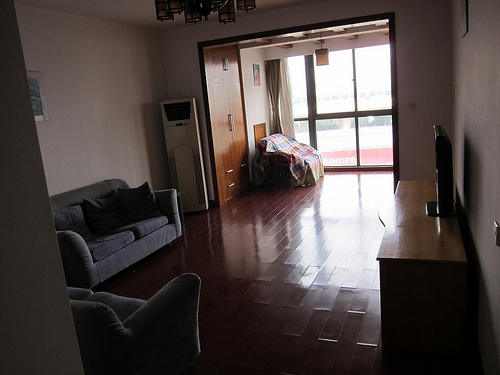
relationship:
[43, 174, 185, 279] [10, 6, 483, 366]
couch in living room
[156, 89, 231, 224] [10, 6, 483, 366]
heater in living room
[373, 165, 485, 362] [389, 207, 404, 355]
cabinet has drawers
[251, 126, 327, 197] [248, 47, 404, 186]
chair by window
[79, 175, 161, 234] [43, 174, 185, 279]
pillows on couch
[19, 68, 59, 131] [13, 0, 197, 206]
artwork on wall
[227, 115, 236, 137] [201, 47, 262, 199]
handles on closet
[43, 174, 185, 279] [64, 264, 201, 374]
sofa next to loveseat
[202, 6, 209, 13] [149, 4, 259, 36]
lamp shade on light fixture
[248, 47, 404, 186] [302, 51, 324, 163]
window has division